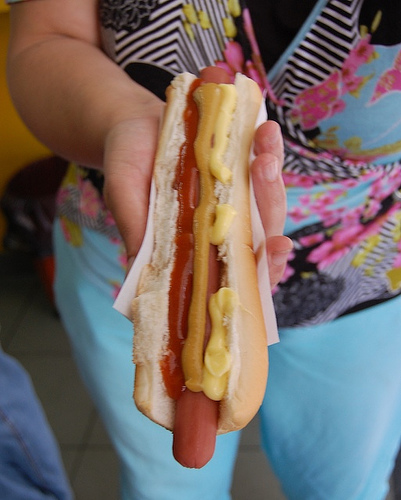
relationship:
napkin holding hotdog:
[113, 96, 281, 347] [150, 69, 260, 397]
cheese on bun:
[206, 85, 234, 405] [131, 70, 268, 434]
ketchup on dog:
[158, 79, 200, 400] [173, 65, 236, 469]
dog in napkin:
[173, 65, 236, 469] [108, 80, 282, 349]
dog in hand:
[173, 65, 236, 469] [97, 107, 288, 298]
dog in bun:
[173, 65, 236, 469] [89, 57, 299, 471]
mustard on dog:
[177, 77, 217, 400] [128, 62, 272, 471]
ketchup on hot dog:
[175, 76, 196, 397] [185, 65, 225, 476]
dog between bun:
[173, 65, 236, 469] [131, 70, 268, 434]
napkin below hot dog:
[113, 96, 281, 347] [177, 60, 232, 466]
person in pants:
[6, 0, 400, 495] [58, 308, 393, 496]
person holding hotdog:
[6, 0, 400, 495] [120, 57, 278, 344]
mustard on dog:
[180, 81, 217, 393] [113, 47, 276, 383]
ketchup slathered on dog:
[158, 79, 200, 400] [173, 65, 236, 469]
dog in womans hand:
[173, 65, 236, 469] [95, 112, 296, 292]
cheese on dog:
[205, 71, 234, 395] [173, 65, 236, 469]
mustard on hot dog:
[180, 81, 217, 393] [169, 61, 242, 475]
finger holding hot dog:
[264, 229, 295, 296] [120, 72, 315, 458]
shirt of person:
[90, 6, 387, 280] [6, 5, 388, 483]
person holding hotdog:
[6, 5, 388, 483] [160, 67, 264, 473]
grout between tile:
[69, 433, 94, 455] [5, 350, 96, 448]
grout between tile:
[69, 433, 94, 455] [67, 439, 126, 496]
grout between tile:
[69, 433, 94, 455] [228, 441, 288, 497]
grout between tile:
[69, 433, 94, 455] [6, 292, 72, 356]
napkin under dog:
[114, 75, 303, 350] [173, 65, 236, 469]